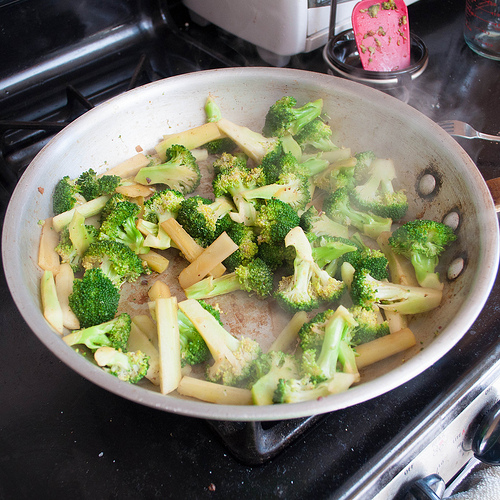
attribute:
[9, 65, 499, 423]
pan — silver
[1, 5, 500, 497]
stove — black, silver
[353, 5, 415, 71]
spatula — red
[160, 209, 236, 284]
potatoes — sliced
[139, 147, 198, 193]
broccoli — cooking, green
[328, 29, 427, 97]
bowl — small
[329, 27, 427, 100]
mug — black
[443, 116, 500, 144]
fork — silver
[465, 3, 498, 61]
cup — glass, black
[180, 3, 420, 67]
toaster — white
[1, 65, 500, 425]
skillet — silver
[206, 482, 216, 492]
crumb — small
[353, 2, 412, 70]
spoon — red